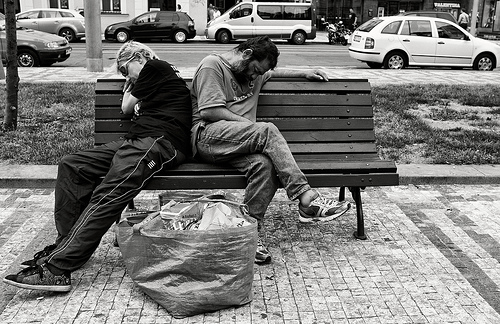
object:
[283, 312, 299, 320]
brick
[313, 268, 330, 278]
brick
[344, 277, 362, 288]
brick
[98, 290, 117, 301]
brick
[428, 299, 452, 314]
brick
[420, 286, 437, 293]
brick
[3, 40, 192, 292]
men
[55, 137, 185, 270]
pants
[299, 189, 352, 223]
shoes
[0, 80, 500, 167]
grass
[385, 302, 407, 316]
brick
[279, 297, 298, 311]
brick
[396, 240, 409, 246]
brick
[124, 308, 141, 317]
brick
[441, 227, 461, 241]
brick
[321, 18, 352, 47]
motorcycle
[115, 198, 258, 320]
bag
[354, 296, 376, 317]
brick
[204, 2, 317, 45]
car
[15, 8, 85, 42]
car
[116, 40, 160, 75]
hair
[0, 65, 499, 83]
curb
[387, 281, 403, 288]
brick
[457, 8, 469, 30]
person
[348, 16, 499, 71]
car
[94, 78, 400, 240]
bench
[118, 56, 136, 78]
wearing glasses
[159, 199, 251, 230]
stuff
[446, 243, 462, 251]
brick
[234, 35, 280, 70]
hair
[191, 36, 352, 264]
man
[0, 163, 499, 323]
ground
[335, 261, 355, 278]
brick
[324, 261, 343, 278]
brick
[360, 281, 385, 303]
brick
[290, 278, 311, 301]
brick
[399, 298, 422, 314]
brick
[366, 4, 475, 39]
store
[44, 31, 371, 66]
road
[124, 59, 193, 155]
shirt